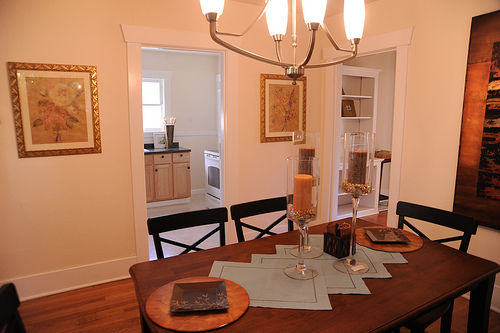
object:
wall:
[5, 3, 140, 289]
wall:
[399, 2, 448, 209]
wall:
[228, 28, 296, 197]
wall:
[125, 0, 231, 42]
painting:
[455, 10, 499, 220]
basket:
[323, 219, 358, 258]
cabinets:
[153, 153, 174, 199]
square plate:
[165, 278, 235, 319]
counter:
[143, 142, 192, 155]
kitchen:
[138, 53, 221, 211]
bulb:
[342, 0, 366, 40]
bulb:
[301, 0, 328, 26]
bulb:
[263, 0, 288, 37]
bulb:
[198, 0, 225, 18]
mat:
[171, 278, 230, 315]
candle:
[346, 147, 370, 183]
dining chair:
[393, 198, 483, 331]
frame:
[388, 40, 408, 222]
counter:
[202, 149, 219, 157]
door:
[132, 47, 233, 259]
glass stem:
[296, 225, 306, 271]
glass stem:
[296, 217, 313, 256]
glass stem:
[344, 199, 361, 268]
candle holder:
[288, 155, 321, 227]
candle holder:
[293, 129, 320, 187]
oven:
[201, 147, 224, 210]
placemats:
[205, 222, 410, 311]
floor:
[23, 281, 134, 333]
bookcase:
[336, 69, 376, 215]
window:
[141, 79, 163, 132]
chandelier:
[196, 0, 367, 87]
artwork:
[260, 70, 308, 143]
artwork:
[5, 60, 102, 160]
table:
[129, 217, 499, 333]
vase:
[341, 127, 373, 190]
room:
[337, 40, 394, 217]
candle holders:
[341, 133, 372, 196]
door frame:
[118, 23, 229, 266]